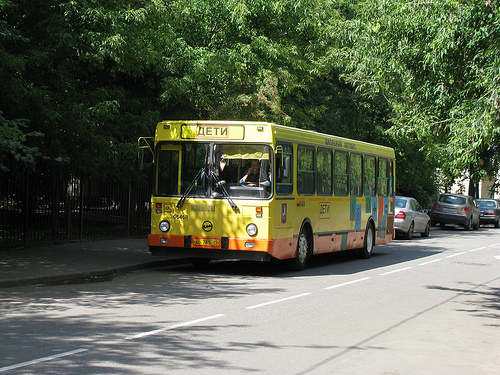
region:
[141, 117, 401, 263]
yellow bus parked on the street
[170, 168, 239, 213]
windshield wipers on front of bus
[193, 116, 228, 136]
black lettering on yellow background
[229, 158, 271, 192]
person driving the bus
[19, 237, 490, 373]
white line painted on the highway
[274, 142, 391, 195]
windows on side of the bus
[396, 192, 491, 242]
cars parked on the street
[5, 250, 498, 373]
shadows of trees on the road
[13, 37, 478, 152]
trees along the sidewalk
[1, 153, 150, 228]
black fence along sidewalk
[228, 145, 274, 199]
bus driver behind the windshield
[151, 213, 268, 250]
headlights on a passenger bus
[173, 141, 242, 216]
bus windshield wipers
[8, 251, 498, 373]
roadway with white dashed lines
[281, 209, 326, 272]
front left wheel well and wheel on a bus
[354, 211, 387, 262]
back left wheel well and wheel on a bus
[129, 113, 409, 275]
mostly yellow city bus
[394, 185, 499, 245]
three vehicles parked on the side of the road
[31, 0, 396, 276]
yellow bus in front of trees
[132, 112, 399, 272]
A yellow and orange bus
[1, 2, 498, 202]
Many green leaves on trees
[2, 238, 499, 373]
White lines on the road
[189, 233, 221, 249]
A yellow license plate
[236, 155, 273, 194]
Driver in the bus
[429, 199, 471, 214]
Two red rear lights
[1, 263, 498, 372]
Shadows on the street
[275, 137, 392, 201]
Windows on side of a bus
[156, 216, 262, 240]
Two headlights on bus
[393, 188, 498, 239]
Three cars in a row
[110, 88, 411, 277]
the bus is yellow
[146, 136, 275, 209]
the bus has a windshield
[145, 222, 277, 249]
the bus has headlights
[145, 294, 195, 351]
the line is white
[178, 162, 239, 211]
the windshield has wipers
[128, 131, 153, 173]
the bus has a mirror attached to it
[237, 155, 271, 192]
the man is driving the bus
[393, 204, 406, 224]
the car has a taillight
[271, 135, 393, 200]
the bus has windows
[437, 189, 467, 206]
the car has a back windshield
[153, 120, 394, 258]
yellow and orange bus along the side of the street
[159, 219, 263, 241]
headlights on the front of the bus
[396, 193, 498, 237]
three cars parked along the side of a city street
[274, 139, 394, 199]
windows along the driver's side of the bus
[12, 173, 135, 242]
black metal fence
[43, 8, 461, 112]
gree trees over the street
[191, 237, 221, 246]
yellow license plate on the front of the bus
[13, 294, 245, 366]
shadows of trees cast on the street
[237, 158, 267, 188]
bus driver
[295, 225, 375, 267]
two wheels on the driver's side of the bus